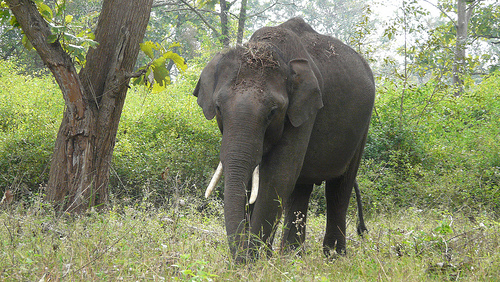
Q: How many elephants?
A: 1.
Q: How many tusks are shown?
A: 2.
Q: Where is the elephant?
A: In grass clearing.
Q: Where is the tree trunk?
A: Left of the elephant.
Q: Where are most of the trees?
A: Behind elephant.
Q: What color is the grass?
A: Green.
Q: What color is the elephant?
A: Grey.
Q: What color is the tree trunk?
A: Brown.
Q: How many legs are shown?
A: 4.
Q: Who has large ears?
A: The elephant.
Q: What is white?
A: Elephant tusks.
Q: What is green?
A: Bushes.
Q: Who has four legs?
A: The elephant.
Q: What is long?
A: The grass.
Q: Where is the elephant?
A: On grassy field.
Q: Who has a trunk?
A: The elephant.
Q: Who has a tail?
A: The elephant.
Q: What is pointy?
A: Elephant's tusks.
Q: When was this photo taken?
A: In the daytime.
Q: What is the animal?
A: Elephant.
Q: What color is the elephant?
A: Grey.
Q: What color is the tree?
A: Brown.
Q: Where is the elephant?
A: Field.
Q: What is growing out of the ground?
A: Grass.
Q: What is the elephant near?
A: Tree.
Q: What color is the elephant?
A: Gray.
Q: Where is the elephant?
A: Near the tree.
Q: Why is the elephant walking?
A: To graze.